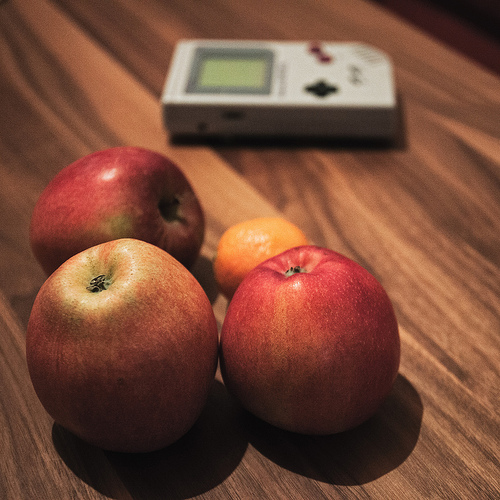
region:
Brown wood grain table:
[397, 271, 482, 316]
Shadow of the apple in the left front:
[61, 456, 238, 494]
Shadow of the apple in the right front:
[262, 440, 432, 485]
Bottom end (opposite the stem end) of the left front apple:
[73, 268, 128, 298]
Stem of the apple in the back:
[148, 187, 195, 227]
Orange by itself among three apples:
[211, 216, 318, 255]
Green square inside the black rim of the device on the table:
[197, 55, 271, 89]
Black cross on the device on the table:
[301, 79, 344, 101]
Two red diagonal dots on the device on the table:
[302, 41, 336, 71]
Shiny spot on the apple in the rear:
[82, 159, 142, 194]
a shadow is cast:
[215, 359, 365, 471]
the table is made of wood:
[400, 210, 455, 306]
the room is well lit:
[1, 15, 471, 490]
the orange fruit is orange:
[210, 215, 305, 260]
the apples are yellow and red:
[40, 226, 405, 461]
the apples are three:
[1, 110, 411, 430]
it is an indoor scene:
[6, 161, 479, 496]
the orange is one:
[207, 223, 332, 285]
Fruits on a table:
[10, 135, 425, 487]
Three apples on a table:
[14, 135, 414, 481]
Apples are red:
[22, 140, 407, 476]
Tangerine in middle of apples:
[204, 200, 319, 297]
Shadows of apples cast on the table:
[42, 425, 437, 498]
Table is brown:
[7, 98, 497, 498]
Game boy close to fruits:
[141, 21, 428, 149]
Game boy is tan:
[148, 29, 422, 162]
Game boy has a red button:
[291, 34, 341, 69]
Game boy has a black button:
[299, 77, 341, 108]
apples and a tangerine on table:
[20, 140, 442, 445]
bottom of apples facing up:
[30, 222, 430, 452]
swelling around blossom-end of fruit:
[25, 226, 170, 342]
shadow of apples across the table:
[40, 360, 450, 490]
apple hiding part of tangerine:
[205, 205, 340, 295]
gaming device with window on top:
[150, 25, 445, 165]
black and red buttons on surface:
[291, 31, 341, 106]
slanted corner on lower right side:
[285, 25, 410, 115]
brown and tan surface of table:
[400, 90, 486, 430]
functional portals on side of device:
[145, 91, 426, 156]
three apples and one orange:
[24, 144, 402, 433]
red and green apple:
[28, 236, 220, 438]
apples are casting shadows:
[33, 375, 426, 492]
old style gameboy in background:
[160, 34, 403, 140]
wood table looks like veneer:
[1, 1, 498, 497]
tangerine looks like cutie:
[216, 215, 306, 285]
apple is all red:
[223, 249, 398, 429]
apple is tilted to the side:
[31, 151, 213, 273]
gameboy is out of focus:
[153, 33, 407, 142]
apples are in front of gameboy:
[29, 31, 409, 444]